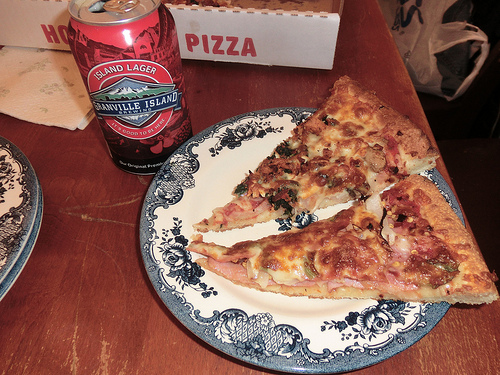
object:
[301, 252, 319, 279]
pepper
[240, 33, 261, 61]
red lettering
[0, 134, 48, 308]
plate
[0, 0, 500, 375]
wooden table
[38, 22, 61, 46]
word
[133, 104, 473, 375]
plate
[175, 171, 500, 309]
pizza slice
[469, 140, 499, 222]
ground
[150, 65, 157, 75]
lettering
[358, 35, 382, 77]
wood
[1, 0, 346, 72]
cardboard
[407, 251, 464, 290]
onion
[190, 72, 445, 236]
pizza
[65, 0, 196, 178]
lager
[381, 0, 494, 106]
plastic bag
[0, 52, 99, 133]
napkins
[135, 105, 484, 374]
edges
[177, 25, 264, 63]
pizza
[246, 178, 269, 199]
ham